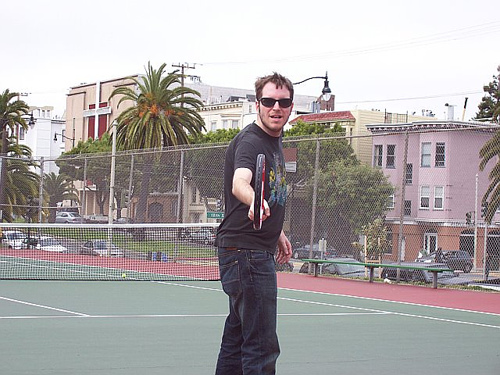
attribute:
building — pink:
[364, 117, 498, 272]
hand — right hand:
[247, 193, 271, 231]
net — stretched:
[0, 220, 221, 281]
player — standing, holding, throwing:
[197, 73, 303, 374]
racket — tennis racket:
[248, 154, 276, 228]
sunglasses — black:
[259, 89, 296, 117]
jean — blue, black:
[215, 251, 281, 373]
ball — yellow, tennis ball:
[121, 269, 133, 281]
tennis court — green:
[6, 125, 499, 371]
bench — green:
[304, 256, 448, 292]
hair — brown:
[257, 72, 293, 101]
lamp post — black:
[283, 69, 334, 101]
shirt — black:
[215, 135, 295, 254]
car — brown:
[306, 257, 368, 280]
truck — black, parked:
[389, 263, 472, 292]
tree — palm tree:
[118, 64, 206, 240]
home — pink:
[62, 64, 499, 265]